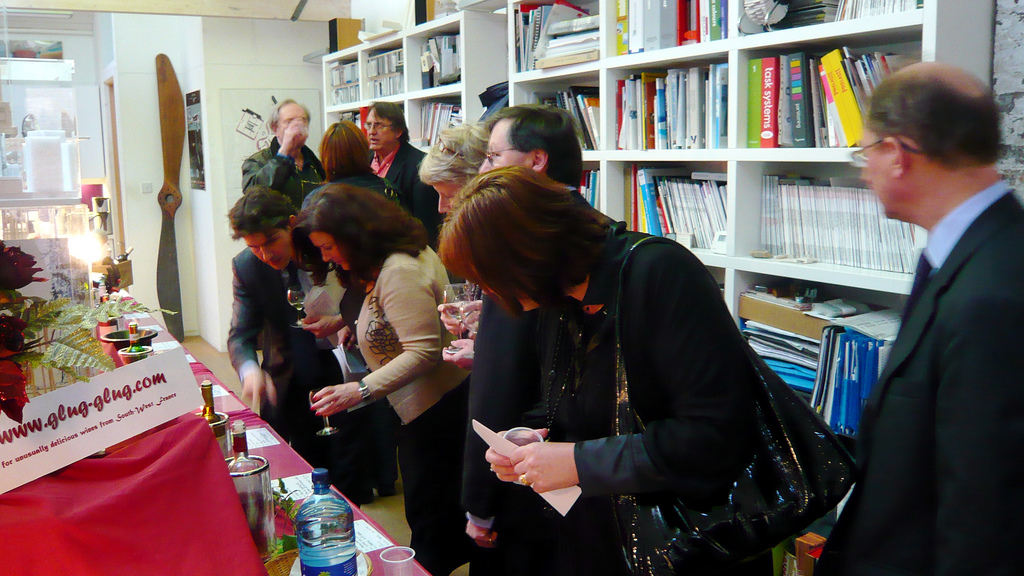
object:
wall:
[198, 21, 329, 354]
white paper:
[469, 419, 582, 517]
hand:
[510, 442, 579, 493]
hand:
[485, 429, 548, 482]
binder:
[819, 49, 868, 148]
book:
[810, 47, 919, 148]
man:
[227, 188, 348, 494]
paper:
[233, 427, 280, 450]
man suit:
[811, 180, 1022, 576]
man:
[479, 104, 619, 224]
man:
[243, 99, 328, 210]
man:
[364, 102, 444, 252]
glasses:
[848, 137, 919, 168]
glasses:
[484, 148, 519, 165]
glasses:
[364, 122, 394, 130]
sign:
[0, 346, 206, 495]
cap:
[312, 468, 332, 494]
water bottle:
[293, 469, 354, 576]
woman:
[293, 184, 473, 576]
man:
[814, 63, 1022, 576]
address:
[0, 374, 176, 470]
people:
[228, 63, 1024, 576]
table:
[0, 297, 436, 576]